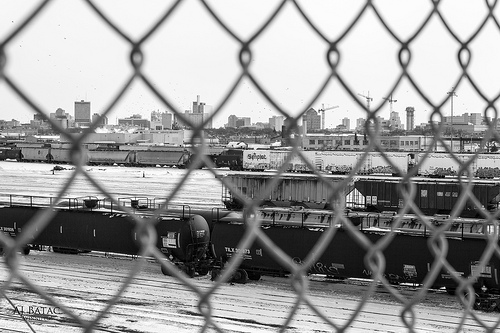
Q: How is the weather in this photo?
A: It is clear.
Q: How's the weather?
A: It is clear.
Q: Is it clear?
A: Yes, it is clear.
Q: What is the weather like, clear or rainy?
A: It is clear.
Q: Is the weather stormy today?
A: No, it is clear.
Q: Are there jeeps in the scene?
A: No, there are no jeeps.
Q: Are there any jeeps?
A: No, there are no jeeps.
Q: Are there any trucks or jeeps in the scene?
A: No, there are no jeeps or trucks.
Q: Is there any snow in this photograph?
A: Yes, there is snow.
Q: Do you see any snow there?
A: Yes, there is snow.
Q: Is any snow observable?
A: Yes, there is snow.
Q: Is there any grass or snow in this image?
A: Yes, there is snow.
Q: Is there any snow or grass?
A: Yes, there is snow.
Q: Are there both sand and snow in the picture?
A: No, there is snow but no sand.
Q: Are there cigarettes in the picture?
A: No, there are no cigarettes.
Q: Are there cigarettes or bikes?
A: No, there are no cigarettes or bikes.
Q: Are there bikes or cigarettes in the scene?
A: No, there are no cigarettes or bikes.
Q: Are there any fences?
A: Yes, there is a fence.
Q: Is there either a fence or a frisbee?
A: Yes, there is a fence.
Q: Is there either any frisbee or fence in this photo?
A: Yes, there is a fence.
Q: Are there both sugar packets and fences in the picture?
A: No, there is a fence but no sugar packets.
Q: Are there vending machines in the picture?
A: No, there are no vending machines.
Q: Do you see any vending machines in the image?
A: No, there are no vending machines.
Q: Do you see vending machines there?
A: No, there are no vending machines.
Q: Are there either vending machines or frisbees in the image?
A: No, there are no vending machines or frisbees.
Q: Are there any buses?
A: No, there are no buses.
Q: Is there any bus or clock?
A: No, there are no buses or clocks.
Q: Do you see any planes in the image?
A: No, there are no planes.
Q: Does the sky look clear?
A: Yes, the sky is clear.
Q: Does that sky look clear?
A: Yes, the sky is clear.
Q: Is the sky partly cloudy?
A: No, the sky is clear.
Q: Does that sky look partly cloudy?
A: No, the sky is clear.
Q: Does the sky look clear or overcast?
A: The sky is clear.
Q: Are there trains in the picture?
A: Yes, there is a train.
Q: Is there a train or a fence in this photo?
A: Yes, there is a train.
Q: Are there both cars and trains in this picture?
A: Yes, there are both a train and a car.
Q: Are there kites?
A: No, there are no kites.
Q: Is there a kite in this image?
A: No, there are no kites.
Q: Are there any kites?
A: No, there are no kites.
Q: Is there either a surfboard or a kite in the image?
A: No, there are no kites or surfboards.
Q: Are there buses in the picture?
A: No, there are no buses.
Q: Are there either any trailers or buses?
A: No, there are no buses or trailers.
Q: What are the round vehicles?
A: The vehicles are cars.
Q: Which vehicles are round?
A: The vehicles are cars.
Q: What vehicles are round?
A: The vehicles are cars.